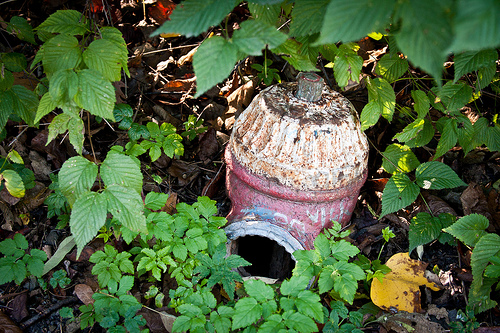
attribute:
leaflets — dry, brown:
[121, 41, 206, 127]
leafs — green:
[69, 190, 109, 264]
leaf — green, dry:
[192, 33, 241, 100]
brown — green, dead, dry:
[133, 43, 192, 115]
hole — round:
[231, 233, 296, 285]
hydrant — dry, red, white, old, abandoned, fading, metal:
[224, 75, 370, 286]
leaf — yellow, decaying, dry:
[371, 251, 442, 317]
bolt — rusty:
[296, 66, 325, 102]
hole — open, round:
[223, 222, 305, 308]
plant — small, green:
[0, 0, 149, 328]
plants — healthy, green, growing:
[0, 0, 224, 333]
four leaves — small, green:
[57, 146, 147, 258]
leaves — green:
[378, 141, 464, 253]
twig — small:
[18, 297, 73, 332]